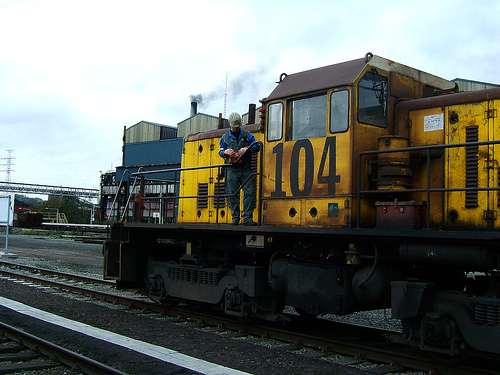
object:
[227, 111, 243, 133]
head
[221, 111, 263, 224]
man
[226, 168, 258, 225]
legs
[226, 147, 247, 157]
hands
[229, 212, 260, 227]
feet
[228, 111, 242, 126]
hat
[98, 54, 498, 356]
train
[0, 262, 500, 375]
tracks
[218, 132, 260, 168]
shirt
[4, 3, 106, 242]
background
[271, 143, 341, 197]
numbers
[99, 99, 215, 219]
building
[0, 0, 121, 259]
background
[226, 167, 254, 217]
pants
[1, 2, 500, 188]
sky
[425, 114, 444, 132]
notice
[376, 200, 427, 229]
box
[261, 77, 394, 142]
window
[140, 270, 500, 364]
wheels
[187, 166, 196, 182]
smoke stack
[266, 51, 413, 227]
booth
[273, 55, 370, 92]
roof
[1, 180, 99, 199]
bridge